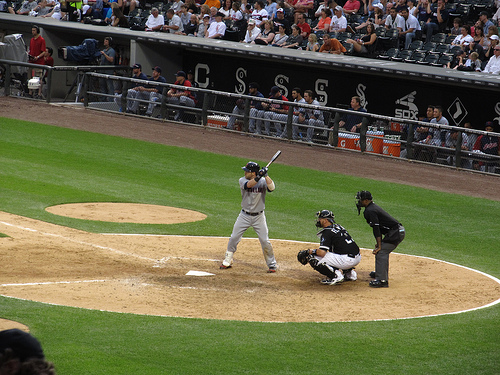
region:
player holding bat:
[210, 141, 295, 271]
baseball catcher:
[284, 205, 366, 293]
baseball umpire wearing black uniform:
[350, 182, 428, 294]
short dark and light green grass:
[411, 188, 463, 223]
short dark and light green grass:
[432, 338, 489, 370]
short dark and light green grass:
[304, 342, 331, 360]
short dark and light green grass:
[97, 322, 158, 362]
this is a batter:
[215, 160, 280, 278]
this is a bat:
[252, 147, 288, 177]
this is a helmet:
[315, 208, 337, 227]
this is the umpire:
[352, 188, 408, 290]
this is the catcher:
[296, 207, 361, 292]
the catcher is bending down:
[295, 208, 362, 291]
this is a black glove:
[295, 244, 312, 271]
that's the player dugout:
[124, 35, 496, 173]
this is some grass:
[1, 121, 498, 373]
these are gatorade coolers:
[335, 128, 405, 160]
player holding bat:
[217, 142, 282, 269]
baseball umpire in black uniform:
[350, 176, 410, 294]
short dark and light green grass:
[37, 132, 81, 162]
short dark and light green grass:
[87, 143, 118, 168]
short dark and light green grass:
[245, 338, 285, 363]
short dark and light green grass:
[130, 333, 172, 367]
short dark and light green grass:
[404, 215, 441, 229]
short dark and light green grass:
[441, 193, 478, 244]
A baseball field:
[26, 25, 476, 369]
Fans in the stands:
[83, 2, 498, 112]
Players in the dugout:
[121, 63, 471, 169]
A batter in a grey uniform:
[215, 130, 280, 283]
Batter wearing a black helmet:
[233, 149, 266, 182]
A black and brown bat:
[251, 139, 296, 185]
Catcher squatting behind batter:
[298, 202, 361, 285]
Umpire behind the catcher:
[355, 181, 409, 290]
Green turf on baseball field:
[48, 139, 176, 201]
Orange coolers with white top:
[332, 109, 407, 164]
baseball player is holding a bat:
[218, 148, 283, 274]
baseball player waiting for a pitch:
[217, 149, 281, 273]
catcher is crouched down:
[297, 208, 362, 284]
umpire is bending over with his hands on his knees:
[352, 187, 404, 287]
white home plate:
[183, 267, 216, 277]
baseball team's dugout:
[52, 31, 495, 172]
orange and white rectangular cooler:
[332, 130, 358, 147]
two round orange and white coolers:
[361, 126, 401, 153]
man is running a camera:
[57, 31, 113, 96]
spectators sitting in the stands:
[2, 0, 499, 81]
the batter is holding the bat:
[221, 148, 282, 273]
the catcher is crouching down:
[296, 208, 359, 284]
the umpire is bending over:
[353, 188, 406, 288]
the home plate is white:
[186, 268, 214, 278]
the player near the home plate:
[185, 160, 275, 278]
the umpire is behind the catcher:
[299, 189, 404, 289]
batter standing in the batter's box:
[220, 151, 280, 273]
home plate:
[185, 267, 215, 277]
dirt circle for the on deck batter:
[46, 200, 208, 224]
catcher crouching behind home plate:
[295, 208, 360, 285]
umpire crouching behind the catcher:
[355, 189, 404, 287]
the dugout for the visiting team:
[87, 35, 498, 174]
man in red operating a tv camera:
[26, 25, 46, 81]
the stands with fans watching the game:
[0, 0, 495, 74]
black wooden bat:
[259, 150, 283, 176]